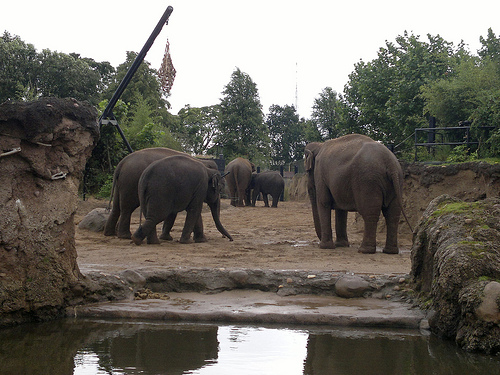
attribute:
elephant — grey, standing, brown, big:
[299, 131, 407, 255]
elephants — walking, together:
[104, 145, 235, 248]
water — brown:
[0, 318, 499, 374]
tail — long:
[389, 169, 421, 238]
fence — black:
[410, 123, 497, 164]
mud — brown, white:
[83, 239, 417, 298]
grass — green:
[439, 199, 492, 258]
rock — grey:
[333, 272, 371, 298]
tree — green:
[214, 69, 269, 172]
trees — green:
[3, 29, 498, 165]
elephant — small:
[251, 171, 285, 209]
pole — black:
[80, 5, 178, 204]